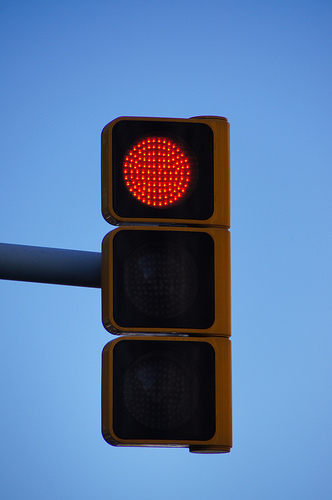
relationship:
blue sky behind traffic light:
[1, 1, 332, 106] [100, 116, 235, 449]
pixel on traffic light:
[140, 137, 149, 144] [100, 116, 235, 449]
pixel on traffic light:
[184, 170, 190, 174] [100, 116, 235, 449]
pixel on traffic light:
[130, 169, 133, 172] [100, 116, 235, 449]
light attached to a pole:
[98, 104, 238, 461] [0, 241, 101, 289]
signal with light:
[66, 112, 309, 424] [125, 134, 228, 201]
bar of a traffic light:
[0, 240, 100, 285] [100, 116, 235, 449]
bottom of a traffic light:
[94, 332, 231, 451] [92, 109, 239, 457]